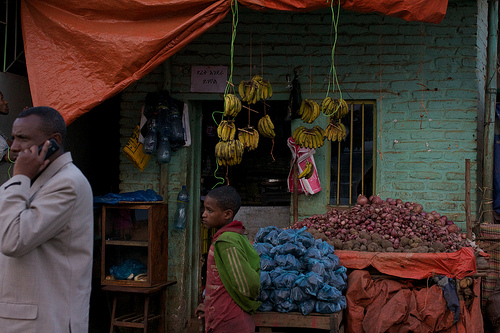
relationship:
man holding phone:
[2, 105, 101, 332] [31, 138, 61, 162]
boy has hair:
[198, 183, 266, 333] [207, 184, 245, 217]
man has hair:
[2, 105, 101, 332] [16, 103, 69, 143]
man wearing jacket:
[2, 105, 101, 332] [1, 153, 96, 332]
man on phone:
[2, 105, 101, 332] [31, 138, 61, 162]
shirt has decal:
[202, 222, 254, 327] [206, 249, 225, 299]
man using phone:
[2, 105, 101, 332] [31, 138, 61, 162]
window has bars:
[326, 97, 376, 205] [327, 99, 372, 207]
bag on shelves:
[96, 189, 163, 206] [96, 195, 166, 290]